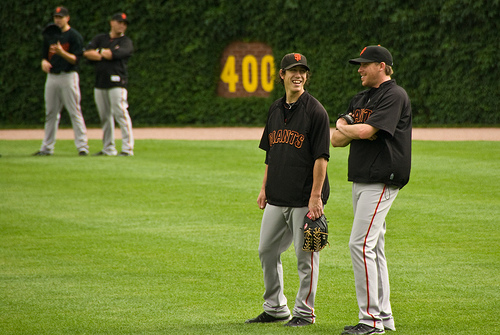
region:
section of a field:
[88, 187, 119, 234]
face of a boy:
[293, 68, 305, 81]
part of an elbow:
[362, 120, 369, 134]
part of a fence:
[195, 23, 225, 55]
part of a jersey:
[288, 163, 301, 170]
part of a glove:
[302, 226, 322, 248]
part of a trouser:
[66, 47, 88, 79]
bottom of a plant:
[448, 78, 472, 84]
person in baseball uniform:
[243, 46, 330, 327]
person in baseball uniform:
[320, 38, 425, 334]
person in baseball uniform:
[82, 5, 144, 159]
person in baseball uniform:
[28, 2, 94, 164]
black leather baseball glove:
[295, 203, 335, 258]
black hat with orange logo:
[279, 49, 311, 75]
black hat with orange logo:
[345, 41, 397, 69]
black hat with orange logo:
[109, 7, 134, 27]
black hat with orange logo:
[50, 4, 75, 23]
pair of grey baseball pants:
[257, 185, 327, 320]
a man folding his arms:
[331, 32, 429, 183]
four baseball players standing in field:
[37, 2, 444, 317]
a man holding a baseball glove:
[273, 52, 339, 284]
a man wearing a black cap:
[280, 47, 317, 83]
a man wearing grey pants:
[315, 56, 417, 333]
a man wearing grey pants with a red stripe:
[258, 44, 327, 326]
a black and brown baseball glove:
[298, 196, 340, 251]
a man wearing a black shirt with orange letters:
[254, 50, 332, 194]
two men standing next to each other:
[12, 11, 142, 160]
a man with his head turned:
[92, 9, 141, 54]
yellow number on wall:
[219, 53, 274, 94]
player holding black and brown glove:
[301, 211, 330, 252]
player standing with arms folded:
[328, 43, 413, 333]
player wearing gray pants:
[347, 180, 397, 331]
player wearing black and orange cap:
[347, 41, 393, 66]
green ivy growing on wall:
[1, 0, 499, 126]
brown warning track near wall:
[0, 124, 499, 141]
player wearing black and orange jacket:
[344, 79, 414, 188]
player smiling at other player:
[242, 50, 330, 327]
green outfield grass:
[1, 139, 499, 333]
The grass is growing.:
[50, 204, 210, 329]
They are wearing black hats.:
[259, 44, 428, 92]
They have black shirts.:
[245, 89, 430, 244]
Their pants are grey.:
[238, 178, 429, 328]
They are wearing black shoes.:
[263, 299, 433, 333]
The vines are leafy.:
[405, 41, 487, 151]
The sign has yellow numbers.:
[195, 39, 295, 126]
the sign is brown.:
[188, 12, 305, 142]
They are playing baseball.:
[34, 9, 437, 330]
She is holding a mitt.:
[303, 208, 328, 254]